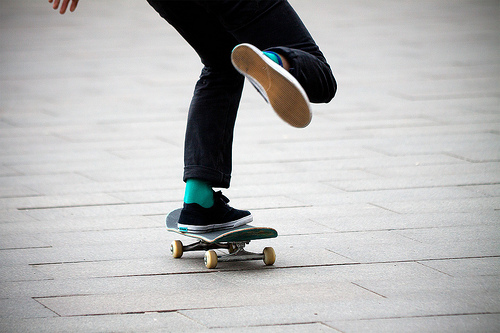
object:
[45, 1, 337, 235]
skater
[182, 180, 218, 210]
sock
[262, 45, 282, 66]
sock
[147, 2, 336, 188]
pants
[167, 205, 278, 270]
skateboard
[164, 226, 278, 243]
edge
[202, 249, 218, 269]
wheel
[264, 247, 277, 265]
wheel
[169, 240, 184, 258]
wheel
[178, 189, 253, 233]
sneaker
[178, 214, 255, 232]
edge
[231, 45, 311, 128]
sole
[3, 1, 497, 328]
ground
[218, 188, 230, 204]
shoelace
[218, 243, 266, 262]
axle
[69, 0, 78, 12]
finger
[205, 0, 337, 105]
leg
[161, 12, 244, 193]
leg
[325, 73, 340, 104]
knee